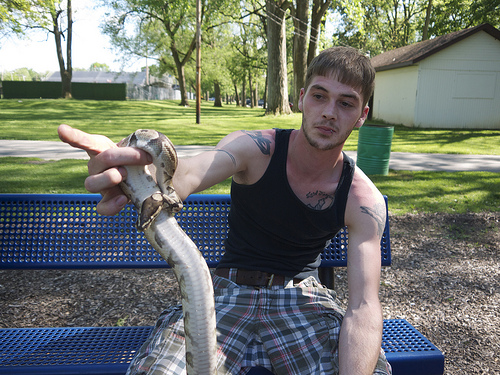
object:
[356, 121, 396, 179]
garbage can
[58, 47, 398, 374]
man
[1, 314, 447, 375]
park bench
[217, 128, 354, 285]
tank top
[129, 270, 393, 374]
shorts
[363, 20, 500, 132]
building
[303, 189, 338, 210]
tatoo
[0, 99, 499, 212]
grass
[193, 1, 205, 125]
pole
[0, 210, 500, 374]
soil insulator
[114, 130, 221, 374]
snake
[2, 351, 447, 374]
edge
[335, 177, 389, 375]
left arm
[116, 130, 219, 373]
body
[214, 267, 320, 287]
belt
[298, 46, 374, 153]
face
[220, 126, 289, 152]
shoulder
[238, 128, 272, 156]
tattoo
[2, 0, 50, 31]
leaves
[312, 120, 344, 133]
mustache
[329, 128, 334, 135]
toothpick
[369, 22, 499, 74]
roof